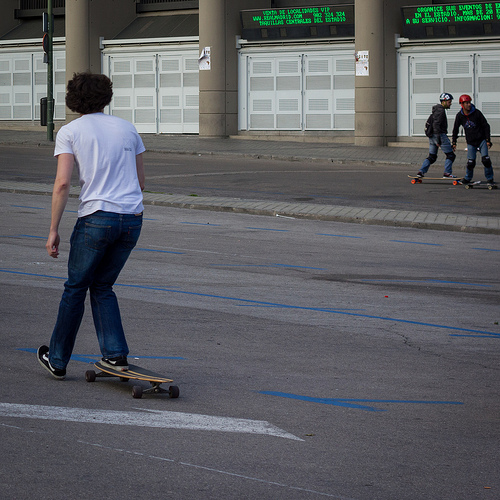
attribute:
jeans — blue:
[416, 132, 458, 179]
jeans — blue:
[463, 140, 494, 187]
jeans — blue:
[24, 207, 150, 381]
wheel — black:
[118, 376, 129, 382]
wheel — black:
[84, 369, 96, 382]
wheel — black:
[167, 384, 179, 399]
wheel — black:
[130, 385, 142, 399]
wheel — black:
[464, 184, 469, 189]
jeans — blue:
[47, 209, 144, 364]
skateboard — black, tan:
[83, 345, 185, 405]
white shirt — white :
[53, 115, 147, 218]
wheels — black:
[123, 381, 184, 401]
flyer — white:
[354, 49, 369, 76]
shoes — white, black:
[31, 328, 127, 385]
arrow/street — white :
[1, 401, 379, 456]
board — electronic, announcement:
[242, 7, 354, 36]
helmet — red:
[456, 95, 473, 106]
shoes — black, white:
[28, 329, 169, 390]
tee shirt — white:
[58, 108, 159, 230]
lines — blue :
[252, 381, 463, 415]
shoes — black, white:
[33, 345, 131, 383]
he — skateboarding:
[15, 59, 167, 407]